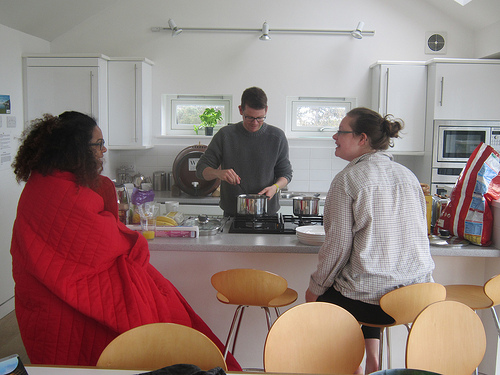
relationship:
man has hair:
[207, 82, 286, 200] [241, 89, 280, 110]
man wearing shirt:
[195, 86, 293, 217] [196, 121, 292, 213]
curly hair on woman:
[11, 110, 104, 193] [21, 102, 115, 204]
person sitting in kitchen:
[306, 107, 435, 299] [0, 4, 495, 251]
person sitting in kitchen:
[197, 87, 292, 194] [0, 4, 495, 251]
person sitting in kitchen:
[9, 111, 195, 323] [0, 4, 495, 251]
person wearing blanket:
[10, 110, 243, 371] [7, 166, 242, 371]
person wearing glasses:
[305, 107, 436, 375] [332, 121, 361, 139]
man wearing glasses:
[195, 86, 293, 217] [238, 110, 272, 126]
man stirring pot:
[195, 86, 293, 217] [237, 192, 267, 213]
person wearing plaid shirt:
[305, 107, 436, 375] [303, 149, 440, 307]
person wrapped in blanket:
[10, 110, 243, 371] [7, 166, 242, 371]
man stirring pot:
[195, 86, 293, 217] [229, 188, 279, 218]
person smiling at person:
[10, 110, 243, 371] [305, 107, 436, 375]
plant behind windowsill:
[198, 102, 224, 125] [159, 90, 236, 141]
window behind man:
[155, 90, 233, 139] [195, 86, 293, 217]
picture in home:
[55, 43, 385, 268] [6, 12, 496, 367]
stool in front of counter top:
[211, 267, 298, 373] [117, 225, 499, 258]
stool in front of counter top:
[357, 281, 447, 371] [117, 225, 499, 258]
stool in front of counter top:
[438, 270, 499, 373] [117, 225, 499, 258]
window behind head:
[284, 96, 358, 141] [229, 87, 273, 137]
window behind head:
[160, 94, 234, 139] [229, 87, 273, 137]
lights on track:
[153, 16, 378, 60] [156, 19, 377, 38]